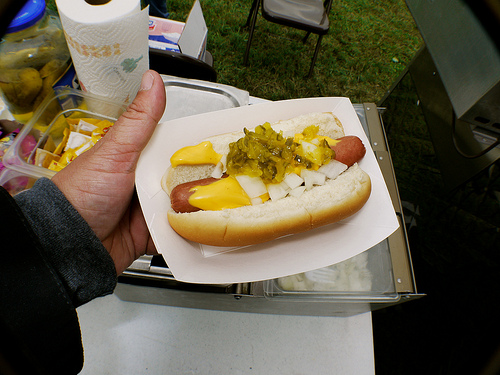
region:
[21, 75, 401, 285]
a man holding a hot dog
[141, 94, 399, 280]
a hot dog on a white paper plate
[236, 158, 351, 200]
bits of white onions on a hot dog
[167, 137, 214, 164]
mustard on a hot dog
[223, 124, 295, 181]
relish on a hot dog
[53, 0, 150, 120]
a roll of paper towl on a table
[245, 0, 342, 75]
a folded chair on a lawn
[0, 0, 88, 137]
pickles in a jar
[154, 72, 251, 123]
a metal tray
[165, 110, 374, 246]
a hot dog with relish, onions and mustard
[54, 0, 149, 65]
paper towel next to condiments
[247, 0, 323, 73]
chair in grass at picknick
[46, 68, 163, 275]
hand holding hotdog in plate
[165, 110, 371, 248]
hotdog in white plate and bun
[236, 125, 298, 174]
relish on top of hotdog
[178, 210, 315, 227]
bun that the hotdog is in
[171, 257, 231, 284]
edge of white plate that hotdog and bun is in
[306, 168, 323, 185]
onions on hotdog and bun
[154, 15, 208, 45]
box of purified water in the grass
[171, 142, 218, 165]
mustard on the bun with hotdog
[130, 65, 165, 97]
short, unpolished man's thumbnail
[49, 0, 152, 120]
roll of paper towels w/ print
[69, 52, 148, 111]
print on paper towels is of vegetables, we can see artichoke, w/ its name written beneath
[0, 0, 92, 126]
jar of vlasic kosher pickles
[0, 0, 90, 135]
pickles are big, in brine; jar has blue label+cap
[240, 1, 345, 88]
1/2 a brown folding chair sits on grass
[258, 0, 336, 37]
chair's seat is unoccupied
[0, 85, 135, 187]
little restaurant supply store bucket of mustard packets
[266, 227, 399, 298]
chopped onions in restaurant supply store bin, covered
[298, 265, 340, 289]
bin visibly includes top of white plastic fork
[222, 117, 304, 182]
there is pickel relish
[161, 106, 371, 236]
the hot dog is dressed in relish, onions and cheese and is sitting inside a cardboard boat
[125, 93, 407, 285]
the cardboard boat is white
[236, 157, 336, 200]
the onions are chopped up and white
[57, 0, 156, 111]
a roll of paper towels sits on the counter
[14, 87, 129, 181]
mustard condiment packages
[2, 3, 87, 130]
big jar of pickles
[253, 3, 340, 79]
the chair is brown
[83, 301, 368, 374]
the table cloth is white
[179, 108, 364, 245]
the hot dog sits inside of the bun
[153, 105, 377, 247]
THIS IS A HOTDOG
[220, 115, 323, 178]
THIS IS PICKLE RELISH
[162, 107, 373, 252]
THIS IS A BUN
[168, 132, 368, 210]
THIS IS A WIENER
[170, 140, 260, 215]
THIS IS YELLOW MUSTARD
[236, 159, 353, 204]
THESE ARE ONIONS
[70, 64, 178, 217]
THIS IS A THUMB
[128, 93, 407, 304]
THE HOTDOG IS IN A CARDBOARD BASKET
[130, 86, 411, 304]
THE BASKET IS WHITE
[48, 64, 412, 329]
THE MAN IS HOLDING THE HOTDOG